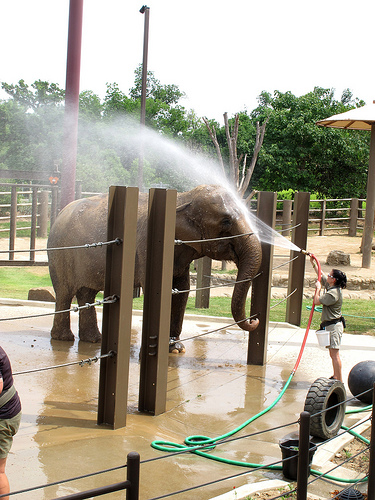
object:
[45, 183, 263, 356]
elephant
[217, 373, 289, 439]
hose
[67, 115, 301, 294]
water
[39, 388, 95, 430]
shadow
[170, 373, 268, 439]
ground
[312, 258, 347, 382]
lady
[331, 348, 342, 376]
leg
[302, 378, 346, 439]
tire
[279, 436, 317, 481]
bucket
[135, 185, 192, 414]
pillar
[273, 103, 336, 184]
tree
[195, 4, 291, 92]
sky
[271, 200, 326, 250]
fence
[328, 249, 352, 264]
rock